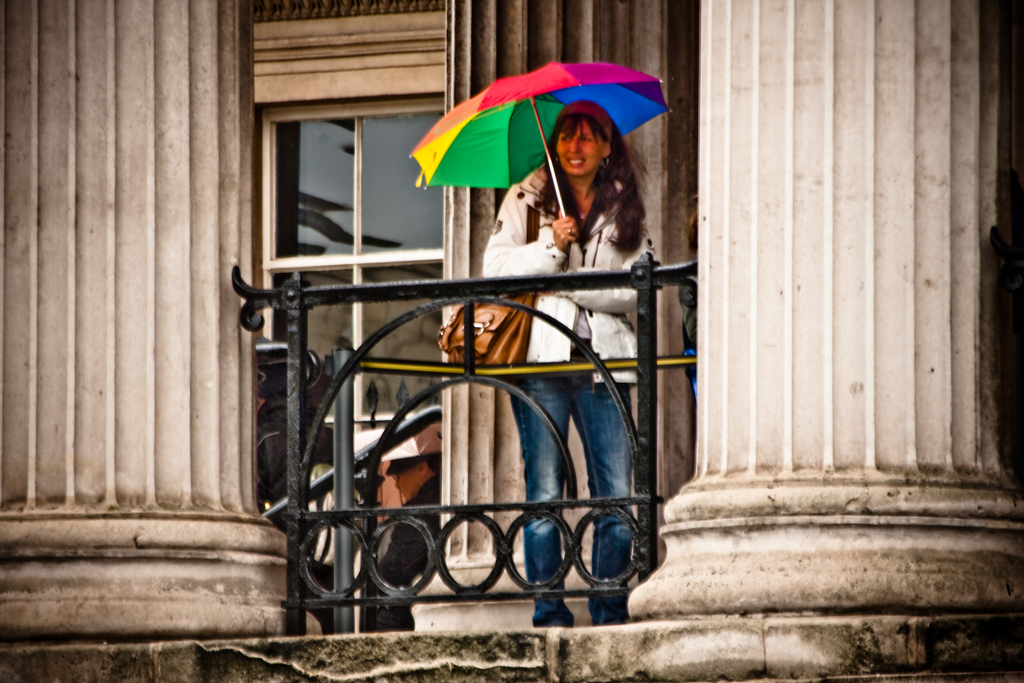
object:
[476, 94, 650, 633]
woman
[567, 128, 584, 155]
nose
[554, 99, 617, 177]
head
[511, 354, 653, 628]
jeans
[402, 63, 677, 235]
umbrella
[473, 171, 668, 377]
coat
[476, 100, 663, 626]
she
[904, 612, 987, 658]
stone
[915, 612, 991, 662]
moss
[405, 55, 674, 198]
fabric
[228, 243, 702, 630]
fence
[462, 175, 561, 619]
woman's side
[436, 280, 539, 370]
bag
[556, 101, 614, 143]
headband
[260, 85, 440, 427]
window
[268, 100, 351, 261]
pane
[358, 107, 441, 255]
pane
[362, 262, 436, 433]
pane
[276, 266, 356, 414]
pane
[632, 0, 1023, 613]
coulmn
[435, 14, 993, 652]
right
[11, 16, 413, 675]
left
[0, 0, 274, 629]
column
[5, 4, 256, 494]
wall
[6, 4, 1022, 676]
building